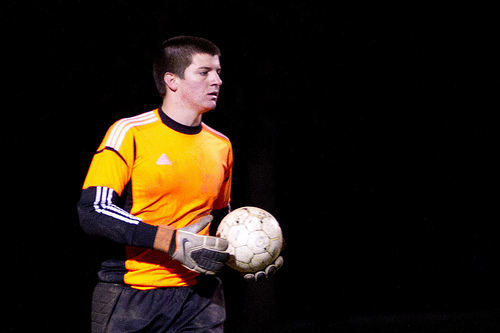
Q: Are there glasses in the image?
A: No, there are no glasses.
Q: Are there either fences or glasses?
A: No, there are no glasses or fences.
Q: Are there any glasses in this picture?
A: No, there are no glasses.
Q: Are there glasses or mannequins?
A: No, there are no glasses or mannequins.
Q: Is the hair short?
A: Yes, the hair is short.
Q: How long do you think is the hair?
A: The hair is short.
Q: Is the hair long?
A: No, the hair is short.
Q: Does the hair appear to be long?
A: No, the hair is short.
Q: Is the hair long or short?
A: The hair is short.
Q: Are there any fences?
A: No, there are no fences.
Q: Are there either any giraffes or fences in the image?
A: No, there are no fences or giraffes.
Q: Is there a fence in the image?
A: No, there are no fences.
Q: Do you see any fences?
A: No, there are no fences.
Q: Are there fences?
A: No, there are no fences.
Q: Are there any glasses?
A: No, there are no glasses.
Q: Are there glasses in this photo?
A: No, there are no glasses.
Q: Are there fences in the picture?
A: No, there are no fences.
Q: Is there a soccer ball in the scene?
A: Yes, there is a soccer ball.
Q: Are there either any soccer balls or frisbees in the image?
A: Yes, there is a soccer ball.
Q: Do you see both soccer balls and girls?
A: No, there is a soccer ball but no girls.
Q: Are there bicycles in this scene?
A: No, there are no bicycles.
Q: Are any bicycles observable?
A: No, there are no bicycles.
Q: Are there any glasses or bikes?
A: No, there are no bikes or glasses.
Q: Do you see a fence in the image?
A: No, there are no fences.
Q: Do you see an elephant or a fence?
A: No, there are no fences or elephants.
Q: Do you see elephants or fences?
A: No, there are no fences or elephants.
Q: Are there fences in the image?
A: No, there are no fences.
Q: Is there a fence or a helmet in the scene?
A: No, there are no fences or helmets.